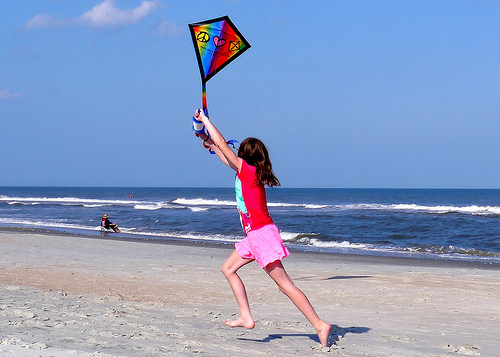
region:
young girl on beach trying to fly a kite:
[156, 8, 365, 343]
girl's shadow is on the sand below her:
[220, 301, 372, 342]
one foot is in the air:
[211, 310, 279, 345]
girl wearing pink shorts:
[232, 220, 292, 273]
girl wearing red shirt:
[215, 157, 291, 229]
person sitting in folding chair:
[67, 206, 142, 272]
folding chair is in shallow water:
[87, 207, 142, 242]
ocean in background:
[287, 175, 477, 256]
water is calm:
[37, 172, 189, 204]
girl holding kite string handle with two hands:
[173, 95, 268, 178]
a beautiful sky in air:
[175, 15, 257, 109]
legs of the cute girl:
[206, 259, 362, 345]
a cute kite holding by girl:
[169, 2, 274, 104]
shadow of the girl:
[268, 315, 398, 352]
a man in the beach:
[81, 196, 143, 246]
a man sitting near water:
[92, 203, 137, 250]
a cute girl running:
[175, 83, 377, 320]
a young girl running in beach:
[175, 107, 346, 340]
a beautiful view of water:
[40, 94, 443, 264]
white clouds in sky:
[40, 0, 180, 47]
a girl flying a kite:
[93, 2, 435, 337]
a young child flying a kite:
[112, 7, 415, 353]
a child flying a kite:
[94, 11, 368, 350]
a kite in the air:
[164, 7, 349, 142]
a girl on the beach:
[123, 29, 445, 350]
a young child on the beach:
[147, 57, 466, 354]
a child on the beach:
[160, 78, 413, 355]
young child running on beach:
[161, 86, 418, 355]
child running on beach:
[79, 53, 450, 349]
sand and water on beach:
[82, 72, 482, 349]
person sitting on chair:
[99, 210, 120, 237]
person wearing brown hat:
[102, 213, 115, 232]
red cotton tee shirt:
[235, 158, 273, 233]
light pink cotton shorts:
[235, 222, 291, 267]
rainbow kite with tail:
[189, 11, 246, 117]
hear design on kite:
[211, 33, 226, 49]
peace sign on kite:
[199, 28, 209, 44]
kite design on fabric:
[230, 39, 240, 49]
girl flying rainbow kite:
[190, 13, 331, 354]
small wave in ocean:
[286, 228, 496, 264]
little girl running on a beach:
[176, 106, 345, 355]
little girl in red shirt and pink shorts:
[192, 105, 342, 347]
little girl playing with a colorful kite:
[175, 95, 337, 346]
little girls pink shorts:
[232, 221, 290, 271]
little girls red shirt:
[220, 154, 288, 232]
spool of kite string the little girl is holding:
[190, 101, 207, 135]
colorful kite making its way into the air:
[184, 10, 254, 121]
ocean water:
[3, 180, 498, 261]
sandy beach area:
[10, 236, 494, 352]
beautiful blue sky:
[29, 42, 482, 152]